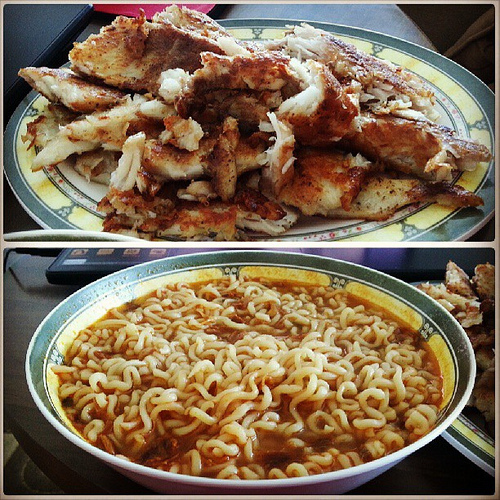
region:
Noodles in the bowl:
[61, 273, 443, 478]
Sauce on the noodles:
[53, 271, 444, 478]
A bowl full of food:
[26, 248, 476, 483]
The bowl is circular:
[26, 250, 474, 486]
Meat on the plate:
[18, 7, 484, 239]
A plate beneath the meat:
[3, 18, 495, 243]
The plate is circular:
[5, 16, 496, 241]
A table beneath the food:
[5, 251, 491, 492]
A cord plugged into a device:
[5, 248, 58, 268]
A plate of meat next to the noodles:
[425, 260, 496, 471]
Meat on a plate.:
[46, 26, 493, 231]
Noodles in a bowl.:
[125, 305, 365, 415]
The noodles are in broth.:
[62, 287, 424, 472]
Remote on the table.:
[33, 239, 283, 281]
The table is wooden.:
[6, 265, 82, 465]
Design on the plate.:
[17, 157, 107, 230]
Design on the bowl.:
[211, 252, 378, 322]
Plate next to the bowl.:
[388, 263, 498, 482]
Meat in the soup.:
[138, 431, 330, 474]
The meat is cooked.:
[436, 261, 496, 448]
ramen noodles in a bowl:
[21, 245, 471, 472]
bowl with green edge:
[15, 249, 485, 479]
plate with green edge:
[8, 10, 498, 246]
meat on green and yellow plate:
[25, 17, 472, 232]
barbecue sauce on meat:
[99, 24, 394, 209]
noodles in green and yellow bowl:
[85, 294, 419, 461]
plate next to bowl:
[436, 268, 498, 475]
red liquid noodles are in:
[67, 274, 437, 476]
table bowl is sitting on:
[7, 251, 482, 499]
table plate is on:
[5, 9, 495, 252]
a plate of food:
[28, 12, 488, 242]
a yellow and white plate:
[18, 20, 486, 245]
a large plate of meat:
[11, 22, 498, 246]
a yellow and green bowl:
[44, 265, 479, 487]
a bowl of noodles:
[33, 260, 455, 479]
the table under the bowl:
[11, 275, 38, 310]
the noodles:
[136, 325, 282, 408]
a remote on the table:
[43, 246, 128, 273]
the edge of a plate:
[452, 305, 497, 465]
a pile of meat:
[14, 38, 474, 228]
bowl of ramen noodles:
[16, 250, 471, 491]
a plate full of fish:
[5, 10, 495, 240]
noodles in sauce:
[60, 281, 437, 472]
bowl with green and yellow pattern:
[30, 250, 475, 480]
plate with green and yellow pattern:
[10, 15, 490, 240]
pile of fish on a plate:
[20, 25, 480, 231]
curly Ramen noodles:
[62, 275, 433, 475]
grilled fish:
[26, 7, 482, 227]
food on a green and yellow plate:
[15, 8, 487, 229]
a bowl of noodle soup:
[25, 253, 475, 487]